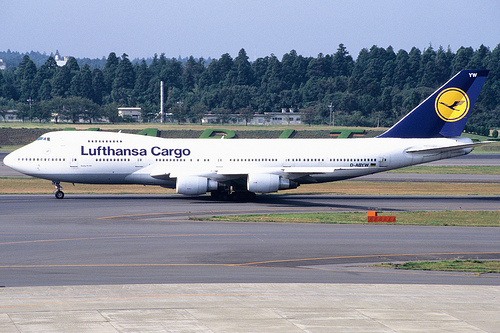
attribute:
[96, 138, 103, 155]
letter — blue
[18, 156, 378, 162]
row — long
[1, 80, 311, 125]
buildings — distant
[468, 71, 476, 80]
yw — small, white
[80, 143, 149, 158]
text — bold, blue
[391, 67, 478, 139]
graphic — very blue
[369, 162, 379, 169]
flag — small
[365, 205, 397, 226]
object — orange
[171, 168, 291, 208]
engines — white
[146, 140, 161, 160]
letter — blue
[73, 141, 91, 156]
letter — blue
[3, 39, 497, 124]
trees — distant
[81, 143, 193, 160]
letters — blue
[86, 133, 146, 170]
letter — blue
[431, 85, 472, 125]
logo — blue, yellow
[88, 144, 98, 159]
letter — blue